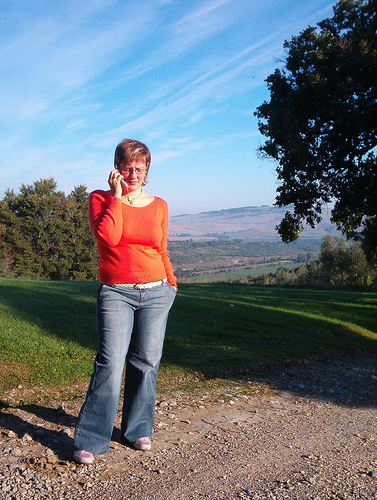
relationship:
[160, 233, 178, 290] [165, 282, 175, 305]
hand in jean pocket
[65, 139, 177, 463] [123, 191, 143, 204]
lady wearing necklace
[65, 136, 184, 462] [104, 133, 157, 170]
lady has hair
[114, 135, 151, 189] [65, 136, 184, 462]
head of lady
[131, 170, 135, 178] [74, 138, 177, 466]
nose of a woman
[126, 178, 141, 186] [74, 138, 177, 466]
mouth of a woman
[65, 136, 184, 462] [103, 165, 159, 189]
lady on phone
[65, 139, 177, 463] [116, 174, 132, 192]
lady on cellphone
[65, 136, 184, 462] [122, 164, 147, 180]
lady wearing glasses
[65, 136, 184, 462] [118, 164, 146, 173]
lady wearing glasses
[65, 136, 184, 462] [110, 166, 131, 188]
lady holding cell phone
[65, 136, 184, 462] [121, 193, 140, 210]
lady wearing chain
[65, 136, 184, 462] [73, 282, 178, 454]
lady wearing blue jeans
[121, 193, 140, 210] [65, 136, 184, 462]
chain on lady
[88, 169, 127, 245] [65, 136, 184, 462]
arm on lady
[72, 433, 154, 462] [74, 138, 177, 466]
feet on woman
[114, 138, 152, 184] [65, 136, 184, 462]
hair on lady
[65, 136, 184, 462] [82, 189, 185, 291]
lady wearing shirt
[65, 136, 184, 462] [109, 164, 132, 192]
lady talking on cell phone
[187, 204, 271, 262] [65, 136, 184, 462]
hills are behind lady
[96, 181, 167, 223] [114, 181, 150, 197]
chain on neck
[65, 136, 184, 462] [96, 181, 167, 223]
lady wearing chain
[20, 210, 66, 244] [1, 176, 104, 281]
leaves are on tree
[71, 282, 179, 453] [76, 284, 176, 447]
blue jeans are on legs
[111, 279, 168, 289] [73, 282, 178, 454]
belt on blue jeans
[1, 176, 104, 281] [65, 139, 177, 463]
tree behind lady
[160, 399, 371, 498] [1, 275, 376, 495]
rocks on ground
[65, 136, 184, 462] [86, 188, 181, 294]
lady wearing shirt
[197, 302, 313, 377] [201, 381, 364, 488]
shadow falls on ground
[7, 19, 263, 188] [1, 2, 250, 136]
clouds in sky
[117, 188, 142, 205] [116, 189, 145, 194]
jewelry on neck